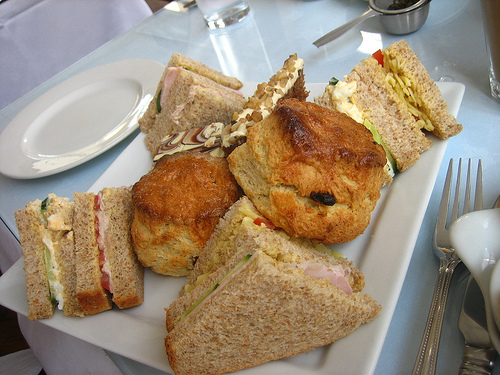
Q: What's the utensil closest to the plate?
A: Fork.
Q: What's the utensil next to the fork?
A: Butterknife.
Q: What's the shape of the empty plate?
A: Round.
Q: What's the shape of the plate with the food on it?
A: Square.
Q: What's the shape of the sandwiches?
A: Triangle.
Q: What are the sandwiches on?
A: The plate.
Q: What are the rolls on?
A: The plate.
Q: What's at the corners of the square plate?
A: Sandwiches.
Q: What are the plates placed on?
A: The table.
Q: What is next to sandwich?
A: Biscuit.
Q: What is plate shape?
A: Round.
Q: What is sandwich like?
A: Cut.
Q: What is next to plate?
A: Fork.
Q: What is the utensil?
A: Fork.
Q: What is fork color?
A: Silver.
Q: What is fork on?
A: Table.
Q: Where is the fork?
A: Beside the plate.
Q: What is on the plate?
A: Sandwiches.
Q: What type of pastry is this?
A: A muffin.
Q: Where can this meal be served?
A: In a restaurant.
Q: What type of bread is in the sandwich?
A: Whole wheat.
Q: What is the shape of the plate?
A: The plate is square.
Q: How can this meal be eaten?
A: With fingers.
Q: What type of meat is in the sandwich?
A: Ham.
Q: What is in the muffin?
A: Raisins.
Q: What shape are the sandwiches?
A: Triangles.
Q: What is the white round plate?
A: Empty.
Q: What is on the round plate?
A: Nothing.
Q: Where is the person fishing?
A: No where.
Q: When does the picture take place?
A: Daytime.